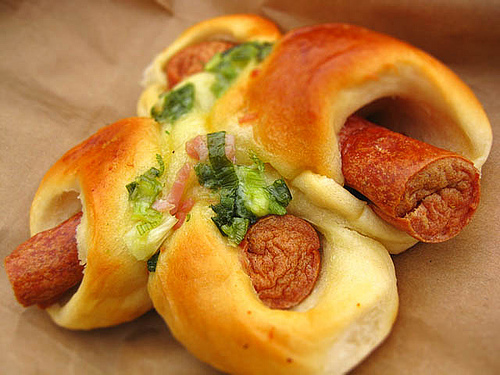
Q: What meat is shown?
A: Sausages.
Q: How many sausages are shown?
A: Four.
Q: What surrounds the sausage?
A: Bread.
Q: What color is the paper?
A: Brown.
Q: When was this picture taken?
A: After cooking.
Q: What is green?
A: Onions.